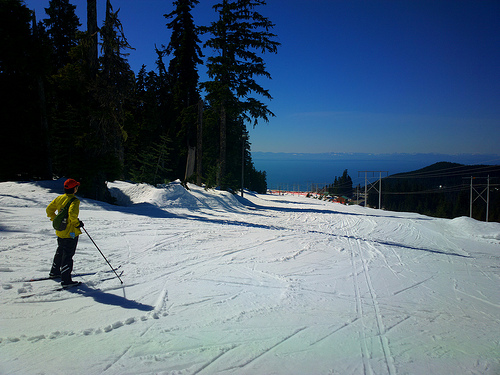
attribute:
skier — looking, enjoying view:
[44, 178, 89, 286]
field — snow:
[1, 173, 500, 374]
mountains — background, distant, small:
[261, 147, 500, 190]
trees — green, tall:
[192, 0, 283, 192]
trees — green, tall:
[151, 0, 207, 186]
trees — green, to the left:
[92, 1, 139, 190]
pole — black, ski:
[77, 222, 128, 285]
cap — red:
[63, 178, 80, 188]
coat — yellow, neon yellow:
[44, 194, 83, 240]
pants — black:
[49, 234, 86, 283]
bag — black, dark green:
[49, 196, 78, 235]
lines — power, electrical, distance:
[272, 156, 500, 198]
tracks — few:
[339, 214, 399, 374]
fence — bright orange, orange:
[268, 191, 314, 195]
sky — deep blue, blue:
[2, 3, 500, 157]